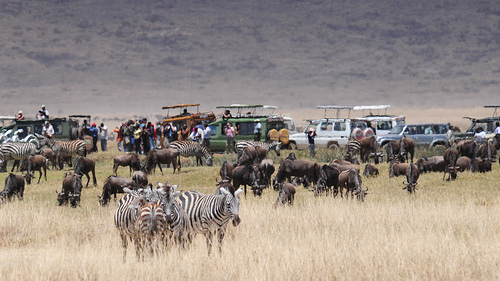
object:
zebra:
[113, 187, 155, 258]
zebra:
[168, 139, 215, 168]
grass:
[241, 197, 496, 280]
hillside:
[0, 0, 497, 111]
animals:
[469, 157, 492, 176]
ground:
[4, 122, 498, 278]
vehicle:
[286, 114, 376, 155]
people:
[251, 128, 264, 143]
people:
[198, 125, 212, 147]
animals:
[150, 186, 190, 261]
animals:
[143, 144, 182, 170]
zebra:
[129, 198, 170, 264]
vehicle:
[371, 121, 461, 156]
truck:
[273, 114, 297, 135]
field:
[2, 206, 498, 279]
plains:
[1, 0, 499, 122]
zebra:
[231, 139, 283, 168]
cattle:
[284, 151, 299, 160]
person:
[223, 121, 239, 153]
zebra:
[0, 136, 42, 170]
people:
[112, 126, 125, 152]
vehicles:
[459, 111, 499, 154]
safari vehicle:
[200, 102, 295, 164]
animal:
[64, 172, 84, 205]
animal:
[55, 171, 71, 203]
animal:
[96, 175, 136, 205]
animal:
[34, 147, 62, 172]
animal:
[130, 167, 152, 194]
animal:
[109, 150, 144, 177]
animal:
[143, 143, 183, 174]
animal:
[168, 136, 214, 167]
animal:
[235, 135, 284, 159]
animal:
[213, 157, 235, 186]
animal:
[228, 162, 264, 199]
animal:
[259, 152, 275, 187]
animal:
[274, 179, 296, 203]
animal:
[273, 157, 315, 180]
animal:
[329, 158, 363, 175]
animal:
[338, 165, 370, 204]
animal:
[361, 160, 378, 175]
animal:
[401, 159, 422, 192]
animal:
[438, 144, 458, 179]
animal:
[456, 133, 479, 160]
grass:
[1, 137, 498, 279]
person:
[303, 123, 322, 159]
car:
[158, 102, 200, 138]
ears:
[231, 186, 245, 196]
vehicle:
[149, 104, 219, 143]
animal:
[0, 170, 30, 200]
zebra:
[45, 137, 90, 165]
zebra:
[174, 185, 244, 253]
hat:
[305, 120, 311, 126]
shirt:
[222, 125, 235, 135]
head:
[218, 182, 243, 226]